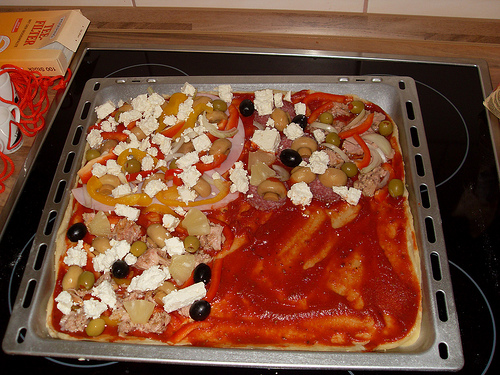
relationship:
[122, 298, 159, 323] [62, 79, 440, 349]
pineapple on pizza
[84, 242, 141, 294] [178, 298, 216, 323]
cheese by olive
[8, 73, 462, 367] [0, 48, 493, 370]
tray on stove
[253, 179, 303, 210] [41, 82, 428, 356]
mushroom on pizza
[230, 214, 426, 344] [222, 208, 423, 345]
sauce on crust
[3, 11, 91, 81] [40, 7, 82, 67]
box of filters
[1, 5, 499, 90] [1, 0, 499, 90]
trim lining wall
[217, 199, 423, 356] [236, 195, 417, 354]
section of pizza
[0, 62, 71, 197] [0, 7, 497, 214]
string on counter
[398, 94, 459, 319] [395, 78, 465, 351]
pan has holes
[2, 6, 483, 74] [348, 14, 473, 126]
wood around stove